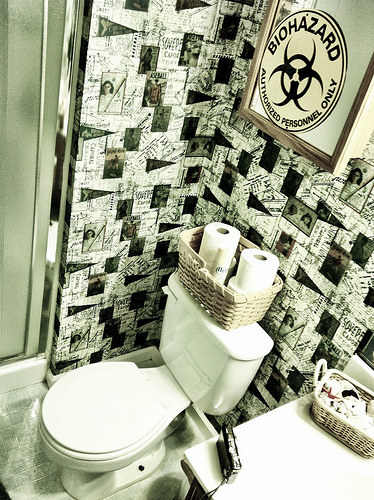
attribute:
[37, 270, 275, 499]
toilet — closed, white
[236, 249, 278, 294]
toilet paper — white, rolled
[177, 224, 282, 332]
basket — small, filled, wicker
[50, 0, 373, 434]
wallpaper — patterned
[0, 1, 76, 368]
door — glass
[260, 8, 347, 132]
picture — black, white, biohazard symbol, biohazard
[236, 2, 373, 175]
mirror — square